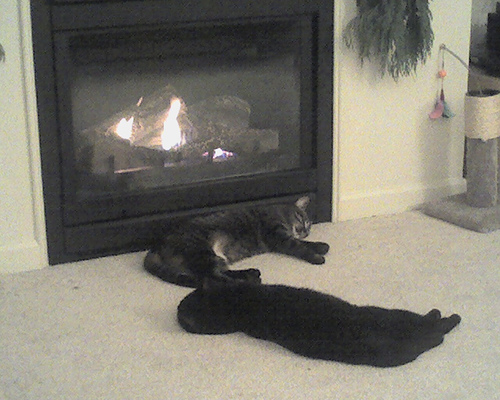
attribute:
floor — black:
[3, 273, 498, 398]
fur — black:
[176, 277, 458, 367]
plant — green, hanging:
[341, 4, 432, 76]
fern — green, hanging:
[337, 0, 437, 84]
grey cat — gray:
[142, 194, 331, 283]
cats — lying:
[138, 192, 468, 375]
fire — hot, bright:
[106, 95, 237, 162]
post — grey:
[421, 85, 499, 232]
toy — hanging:
[431, 44, 456, 126]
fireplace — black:
[38, 11, 330, 251]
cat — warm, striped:
[143, 194, 333, 286]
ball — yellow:
[431, 64, 447, 81]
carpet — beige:
[361, 225, 466, 293]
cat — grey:
[178, 185, 335, 282]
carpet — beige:
[26, 257, 490, 398]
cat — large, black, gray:
[191, 265, 456, 370]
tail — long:
[145, 251, 190, 284]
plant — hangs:
[348, 0, 433, 92]